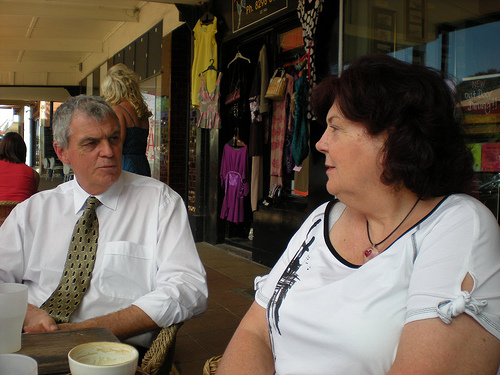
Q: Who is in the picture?
A: A man and a woman.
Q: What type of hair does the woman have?
A: Black.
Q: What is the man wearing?
A: A tie.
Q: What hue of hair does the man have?
A: Gray.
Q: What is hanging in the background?
A: Clothes.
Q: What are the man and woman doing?
A: Talking.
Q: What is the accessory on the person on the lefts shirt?
A: Tie.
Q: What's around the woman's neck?
A: Necklace.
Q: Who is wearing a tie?
A: The man.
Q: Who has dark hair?
A: The woman.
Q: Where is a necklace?
A: Around woman's neck.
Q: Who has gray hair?
A: A man.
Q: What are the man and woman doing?
A: Talking.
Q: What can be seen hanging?
A: Dresses and purses.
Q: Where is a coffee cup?
A: On the table.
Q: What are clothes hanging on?
A: Hangers.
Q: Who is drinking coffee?
A: People.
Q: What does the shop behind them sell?
A: Clothing.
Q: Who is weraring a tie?
A: Man.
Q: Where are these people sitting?
A: Cafe.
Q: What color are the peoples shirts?
A: White.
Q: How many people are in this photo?
A: Four.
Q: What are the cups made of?
A: Styrofoam.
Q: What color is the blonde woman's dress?
A: Blue.